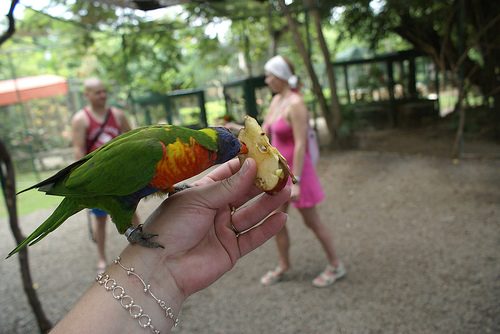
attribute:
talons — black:
[120, 225, 168, 248]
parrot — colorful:
[9, 112, 249, 257]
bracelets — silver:
[94, 266, 165, 332]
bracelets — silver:
[111, 251, 186, 328]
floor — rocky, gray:
[379, 173, 466, 303]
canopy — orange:
[0, 73, 67, 105]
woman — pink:
[248, 49, 352, 294]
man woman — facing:
[35, 48, 327, 128]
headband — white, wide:
[253, 60, 328, 104]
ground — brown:
[167, 137, 498, 329]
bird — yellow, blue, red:
[28, 65, 235, 260]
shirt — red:
[83, 107, 120, 154]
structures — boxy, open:
[328, 47, 441, 124]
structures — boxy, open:
[222, 68, 275, 125]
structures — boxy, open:
[130, 87, 208, 131]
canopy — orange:
[0, 77, 73, 102]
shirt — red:
[73, 105, 148, 178]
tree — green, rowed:
[119, 21, 179, 123]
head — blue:
[211, 125, 246, 160]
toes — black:
[258, 243, 389, 298]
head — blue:
[213, 126, 248, 165]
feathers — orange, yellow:
[20, 122, 216, 195]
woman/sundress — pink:
[256, 49, 346, 289]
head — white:
[77, 75, 114, 112]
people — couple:
[65, 50, 354, 292]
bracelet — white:
[113, 252, 180, 326]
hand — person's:
[144, 154, 288, 304]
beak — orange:
[238, 139, 251, 155]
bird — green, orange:
[3, 120, 253, 260]